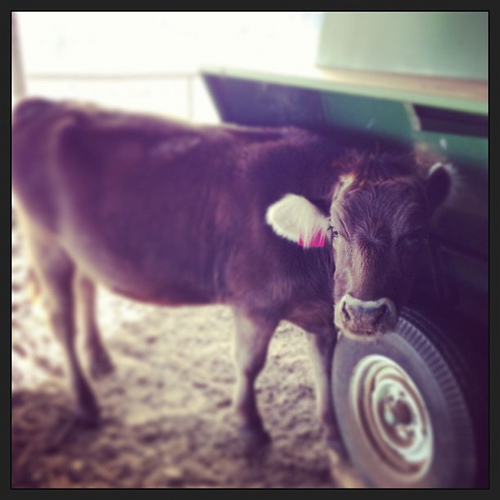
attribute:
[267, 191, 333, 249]
ear — big, large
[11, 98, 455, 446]
cow — brown, standing, young, looking, furry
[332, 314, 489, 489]
tire — black, small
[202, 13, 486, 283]
vehicle — green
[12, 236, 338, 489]
dirt — gray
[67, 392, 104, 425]
hooves — black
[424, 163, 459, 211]
ear — red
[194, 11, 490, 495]
truck — green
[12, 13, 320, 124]
window — clear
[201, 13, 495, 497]
machine — green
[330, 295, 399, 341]
snout — white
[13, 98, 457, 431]
hair — brown